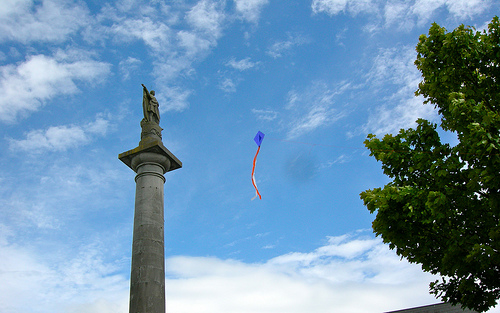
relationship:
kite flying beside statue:
[249, 125, 265, 201] [111, 74, 187, 309]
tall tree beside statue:
[359, 14, 500, 310] [136, 87, 170, 167]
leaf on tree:
[374, 148, 384, 158] [364, 114, 491, 274]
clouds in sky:
[2, 2, 498, 307] [0, 0, 499, 310]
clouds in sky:
[2, 2, 498, 307] [2, 8, 401, 74]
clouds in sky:
[2, 2, 498, 307] [280, 172, 336, 212]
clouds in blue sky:
[2, 2, 498, 307] [187, 197, 247, 226]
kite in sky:
[249, 125, 265, 201] [0, 0, 499, 310]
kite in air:
[245, 125, 270, 198] [190, 47, 333, 300]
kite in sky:
[249, 125, 265, 201] [174, 22, 364, 296]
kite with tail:
[249, 125, 265, 201] [247, 141, 263, 203]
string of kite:
[249, 148, 264, 204] [234, 129, 294, 204]